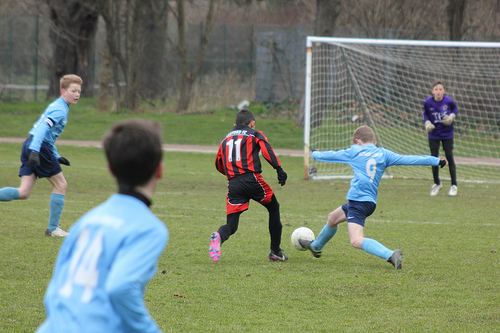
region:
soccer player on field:
[301, 124, 448, 264]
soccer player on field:
[205, 103, 295, 271]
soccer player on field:
[31, 120, 176, 327]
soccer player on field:
[1, 74, 84, 244]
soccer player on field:
[420, 78, 462, 198]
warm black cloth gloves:
[26, 152, 43, 170]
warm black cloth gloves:
[58, 155, 70, 169]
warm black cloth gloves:
[274, 168, 290, 185]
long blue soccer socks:
[47, 192, 65, 231]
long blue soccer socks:
[356, 236, 392, 261]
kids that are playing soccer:
[58, 50, 495, 312]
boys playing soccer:
[8, 51, 360, 318]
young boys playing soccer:
[28, 55, 494, 332]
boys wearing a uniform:
[21, 44, 493, 276]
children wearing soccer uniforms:
[37, 62, 414, 307]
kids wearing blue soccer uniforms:
[11, 56, 458, 332]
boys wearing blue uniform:
[52, 63, 437, 307]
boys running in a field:
[4, 58, 306, 321]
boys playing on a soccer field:
[58, 79, 483, 326]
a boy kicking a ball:
[221, 86, 499, 321]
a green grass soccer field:
[0, 140, 499, 331]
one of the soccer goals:
[302, 36, 498, 180]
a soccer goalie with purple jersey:
[422, 80, 458, 196]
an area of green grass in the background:
[0, 98, 499, 158]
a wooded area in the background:
[0, 0, 499, 140]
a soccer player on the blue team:
[0, 73, 82, 236]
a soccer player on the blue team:
[33, 119, 168, 331]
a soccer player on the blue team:
[297, 125, 448, 270]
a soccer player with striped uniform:
[207, 108, 286, 263]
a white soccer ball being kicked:
[290, 225, 315, 251]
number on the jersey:
[216, 140, 252, 167]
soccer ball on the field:
[288, 220, 314, 250]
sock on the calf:
[362, 238, 391, 258]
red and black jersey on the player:
[214, 133, 259, 173]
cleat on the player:
[207, 229, 222, 259]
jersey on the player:
[352, 150, 383, 200]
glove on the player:
[28, 153, 38, 165]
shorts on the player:
[223, 174, 270, 211]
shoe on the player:
[300, 233, 317, 255]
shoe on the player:
[451, 184, 456, 197]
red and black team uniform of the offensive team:
[215, 130, 289, 212]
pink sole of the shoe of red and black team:
[210, 232, 220, 261]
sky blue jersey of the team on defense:
[27, 192, 174, 332]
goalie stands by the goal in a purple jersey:
[421, 82, 461, 194]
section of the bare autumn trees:
[37, 0, 159, 110]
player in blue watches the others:
[1, 73, 81, 235]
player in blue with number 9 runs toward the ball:
[298, 126, 449, 270]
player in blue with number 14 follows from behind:
[31, 122, 170, 332]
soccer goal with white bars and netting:
[305, 37, 497, 181]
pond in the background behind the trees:
[5, 82, 142, 102]